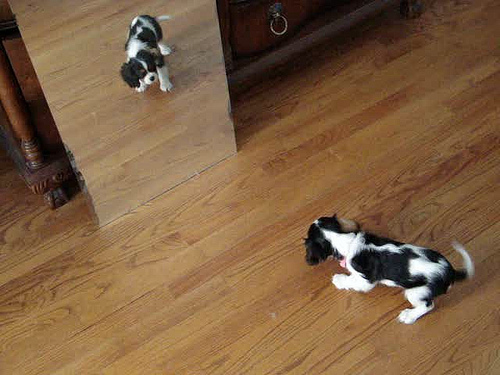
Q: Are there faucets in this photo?
A: No, there are no faucets.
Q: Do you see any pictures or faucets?
A: No, there are no faucets or pictures.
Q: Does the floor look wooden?
A: Yes, the floor is wooden.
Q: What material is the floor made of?
A: The floor is made of wood.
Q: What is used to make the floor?
A: The floor is made of wood.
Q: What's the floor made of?
A: The floor is made of wood.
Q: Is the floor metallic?
A: No, the floor is wooden.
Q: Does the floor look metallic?
A: No, the floor is wooden.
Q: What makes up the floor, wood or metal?
A: The floor is made of wood.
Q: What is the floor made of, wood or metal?
A: The floor is made of wood.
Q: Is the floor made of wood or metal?
A: The floor is made of wood.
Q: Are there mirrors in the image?
A: Yes, there is a mirror.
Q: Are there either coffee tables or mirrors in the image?
A: Yes, there is a mirror.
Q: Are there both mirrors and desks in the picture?
A: No, there is a mirror but no desks.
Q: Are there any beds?
A: No, there are no beds.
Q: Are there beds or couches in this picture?
A: No, there are no beds or couches.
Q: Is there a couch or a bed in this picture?
A: No, there are no beds or couches.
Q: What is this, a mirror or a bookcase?
A: This is a mirror.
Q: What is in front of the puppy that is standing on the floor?
A: The mirror is in front of the puppy.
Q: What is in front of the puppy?
A: The mirror is in front of the puppy.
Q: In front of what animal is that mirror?
A: The mirror is in front of the puppy.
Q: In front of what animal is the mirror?
A: The mirror is in front of the puppy.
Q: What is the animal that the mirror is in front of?
A: The animal is a puppy.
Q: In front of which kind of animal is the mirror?
A: The mirror is in front of the puppy.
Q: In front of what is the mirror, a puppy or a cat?
A: The mirror is in front of a puppy.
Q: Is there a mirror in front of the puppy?
A: Yes, there is a mirror in front of the puppy.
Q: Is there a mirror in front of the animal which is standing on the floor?
A: Yes, there is a mirror in front of the puppy.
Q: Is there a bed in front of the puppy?
A: No, there is a mirror in front of the puppy.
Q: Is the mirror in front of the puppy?
A: Yes, the mirror is in front of the puppy.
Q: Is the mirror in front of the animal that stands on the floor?
A: Yes, the mirror is in front of the puppy.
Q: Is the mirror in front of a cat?
A: No, the mirror is in front of the puppy.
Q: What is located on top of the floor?
A: The mirror is on top of the floor.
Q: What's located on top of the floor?
A: The mirror is on top of the floor.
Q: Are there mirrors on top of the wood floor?
A: Yes, there is a mirror on top of the floor.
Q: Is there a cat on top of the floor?
A: No, there is a mirror on top of the floor.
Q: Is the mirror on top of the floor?
A: Yes, the mirror is on top of the floor.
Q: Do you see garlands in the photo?
A: No, there are no garlands.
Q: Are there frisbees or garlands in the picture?
A: No, there are no garlands or frisbees.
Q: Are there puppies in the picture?
A: Yes, there is a puppy.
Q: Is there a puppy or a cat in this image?
A: Yes, there is a puppy.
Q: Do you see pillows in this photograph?
A: No, there are no pillows.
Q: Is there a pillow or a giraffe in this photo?
A: No, there are no pillows or giraffes.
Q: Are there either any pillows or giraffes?
A: No, there are no pillows or giraffes.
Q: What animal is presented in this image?
A: The animal is a puppy.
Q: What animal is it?
A: The animal is a puppy.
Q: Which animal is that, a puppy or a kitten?
A: That is a puppy.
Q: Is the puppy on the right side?
A: Yes, the puppy is on the right of the image.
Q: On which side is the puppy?
A: The puppy is on the right of the image.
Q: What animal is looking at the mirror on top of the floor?
A: The puppy is looking at the mirror.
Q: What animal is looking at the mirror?
A: The puppy is looking at the mirror.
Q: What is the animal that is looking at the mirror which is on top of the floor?
A: The animal is a puppy.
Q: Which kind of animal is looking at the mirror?
A: The animal is a puppy.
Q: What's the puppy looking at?
A: The puppy is looking at the mirror.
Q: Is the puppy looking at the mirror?
A: Yes, the puppy is looking at the mirror.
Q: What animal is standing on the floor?
A: The puppy is standing on the floor.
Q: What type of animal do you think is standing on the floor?
A: The animal is a puppy.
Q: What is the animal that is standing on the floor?
A: The animal is a puppy.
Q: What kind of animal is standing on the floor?
A: The animal is a puppy.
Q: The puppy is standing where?
A: The puppy is standing on the floor.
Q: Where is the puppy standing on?
A: The puppy is standing on the floor.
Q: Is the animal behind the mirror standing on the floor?
A: Yes, the puppy is standing on the floor.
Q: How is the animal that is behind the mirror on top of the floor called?
A: The animal is a puppy.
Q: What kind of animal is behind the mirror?
A: The animal is a puppy.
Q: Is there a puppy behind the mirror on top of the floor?
A: Yes, there is a puppy behind the mirror.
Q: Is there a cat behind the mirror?
A: No, there is a puppy behind the mirror.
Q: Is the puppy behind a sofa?
A: No, the puppy is behind the mirror.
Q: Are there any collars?
A: Yes, there is a collar.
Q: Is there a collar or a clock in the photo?
A: Yes, there is a collar.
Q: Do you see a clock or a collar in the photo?
A: Yes, there is a collar.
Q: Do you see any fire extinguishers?
A: No, there are no fire extinguishers.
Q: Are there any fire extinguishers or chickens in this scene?
A: No, there are no fire extinguishers or chickens.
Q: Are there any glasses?
A: No, there are no glasses.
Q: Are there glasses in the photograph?
A: No, there are no glasses.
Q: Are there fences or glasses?
A: No, there are no glasses or fences.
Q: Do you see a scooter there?
A: No, there are no scooters.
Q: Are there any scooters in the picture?
A: No, there are no scooters.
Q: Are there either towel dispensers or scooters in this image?
A: No, there are no scooters or towel dispensers.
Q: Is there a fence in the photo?
A: No, there are no fences.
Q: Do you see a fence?
A: No, there are no fences.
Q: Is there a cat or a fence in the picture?
A: No, there are no fences or cats.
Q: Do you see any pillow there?
A: No, there are no pillows.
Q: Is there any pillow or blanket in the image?
A: No, there are no pillows or blankets.